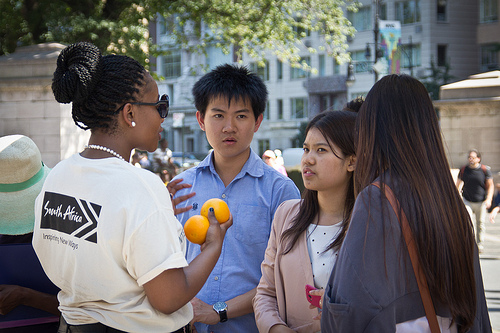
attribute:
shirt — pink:
[249, 196, 348, 331]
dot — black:
[322, 228, 326, 233]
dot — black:
[310, 234, 315, 244]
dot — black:
[315, 250, 320, 255]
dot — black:
[322, 262, 329, 266]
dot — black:
[335, 251, 338, 258]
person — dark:
[323, 85, 450, 323]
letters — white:
[41, 197, 85, 224]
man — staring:
[24, 28, 499, 329]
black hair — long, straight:
[339, 69, 481, 330]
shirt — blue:
[168, 148, 300, 331]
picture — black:
[37, 182, 105, 242]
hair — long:
[343, 76, 492, 325]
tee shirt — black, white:
[17, 149, 245, 329]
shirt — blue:
[173, 158, 293, 325]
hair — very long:
[356, 72, 478, 320]